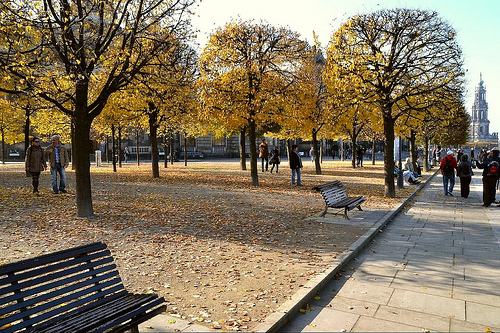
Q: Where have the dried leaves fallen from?
A: From the trees.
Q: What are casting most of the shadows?
A: The trees.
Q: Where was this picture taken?
A: Park.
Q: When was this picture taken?
A: Autumn.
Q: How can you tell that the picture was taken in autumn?
A: The leaves are yellowing and falling off the trees.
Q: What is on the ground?
A: Dead leaves.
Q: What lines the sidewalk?
A: Benches.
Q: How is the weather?
A: Clear.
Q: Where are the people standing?
A: All over the park.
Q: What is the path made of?
A: Stone.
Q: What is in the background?
A: Buildings.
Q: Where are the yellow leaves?
A: In the trees and on the ground.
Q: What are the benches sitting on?
A: Concrete pads.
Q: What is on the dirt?
A: Fallen leaves.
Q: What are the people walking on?
A: Sidewalk.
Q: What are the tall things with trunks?
A: Trees.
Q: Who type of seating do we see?
A: Benches.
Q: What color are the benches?
A: Black.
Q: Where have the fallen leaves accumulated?
A: Under the trees.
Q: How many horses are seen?
A: None.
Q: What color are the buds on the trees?
A: Yellow.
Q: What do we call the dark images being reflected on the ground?
A: Shadows.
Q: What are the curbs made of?
A: Concrete.